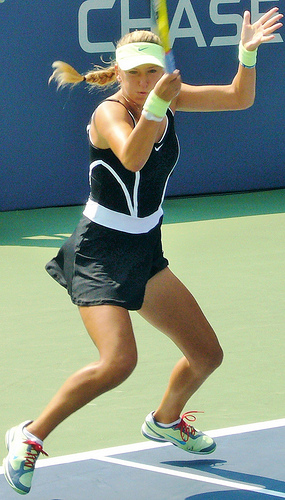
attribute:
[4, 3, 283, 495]
woman — playing, young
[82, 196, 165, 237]
band — white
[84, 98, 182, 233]
shirt — black, white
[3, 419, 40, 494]
shoe — yellow, green, gray, blue, red, white,, white, black, & red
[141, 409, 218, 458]
shoe — yellow, green, gray, blue, red, white,, white, black, & red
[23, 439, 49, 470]
lace — red, pink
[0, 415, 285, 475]
stripe — white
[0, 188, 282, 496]
tennis court — blue, green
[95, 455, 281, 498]
stripe — white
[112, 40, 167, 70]
hat — green, lime green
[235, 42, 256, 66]
wrist band — yellow, green, lime green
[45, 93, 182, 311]
tennis dress — black, white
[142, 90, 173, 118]
wrist band — yellow, green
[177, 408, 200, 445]
lace — red, pink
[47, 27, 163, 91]
hair — braided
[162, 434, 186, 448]
logo — blue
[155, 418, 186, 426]
sock — white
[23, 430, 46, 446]
sock — white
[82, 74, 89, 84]
hair band — black